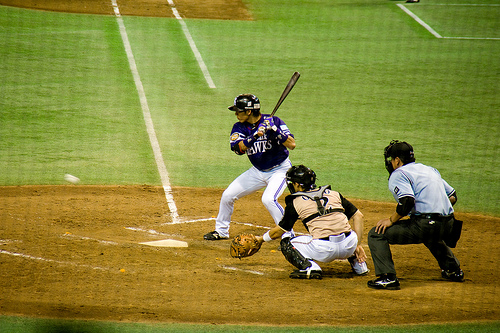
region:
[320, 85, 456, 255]
a man playing as usher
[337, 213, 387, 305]
a man playing as usher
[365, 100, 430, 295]
a man playing as usher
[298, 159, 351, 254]
a man playing baseball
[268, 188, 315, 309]
a man playing baseball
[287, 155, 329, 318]
a man playing baseball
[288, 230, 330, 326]
a man playing baseball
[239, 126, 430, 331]
the men are playing baseball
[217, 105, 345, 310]
the men are playing baseball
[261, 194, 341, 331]
the men are playing baseball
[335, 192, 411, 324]
the men are playing baseball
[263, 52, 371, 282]
the men are playing baseball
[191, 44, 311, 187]
man with a bat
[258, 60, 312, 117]
bat in man's hand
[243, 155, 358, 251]
catcher behind the plate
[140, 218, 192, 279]
plate under the batter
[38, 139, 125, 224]
ball approaching the plate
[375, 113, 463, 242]
umpire behind the catcher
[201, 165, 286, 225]
pants on the player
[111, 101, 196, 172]
first base line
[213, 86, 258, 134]
helmet on the player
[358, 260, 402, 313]
left shoe of the umpire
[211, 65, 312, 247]
a baseball player at bat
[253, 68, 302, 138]
a black baseball bat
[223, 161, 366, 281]
a crouching baseball catcher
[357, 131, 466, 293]
a crouching baseball umpire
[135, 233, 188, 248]
a baseball home plate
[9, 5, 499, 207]
a green grass field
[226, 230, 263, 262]
a brown leather catcher's mit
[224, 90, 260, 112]
a black protective helmet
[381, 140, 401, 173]
a protective face mask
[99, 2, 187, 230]
a white chalk line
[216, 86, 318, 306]
a man playing baseball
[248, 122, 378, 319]
a man playing baseball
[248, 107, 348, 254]
a man playing baseball